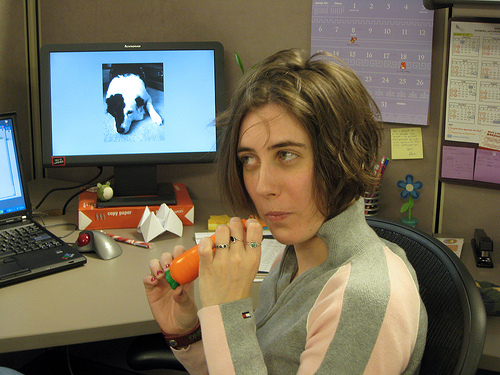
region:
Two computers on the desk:
[0, 30, 240, 283]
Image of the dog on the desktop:
[43, 22, 216, 159]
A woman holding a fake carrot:
[143, 45, 400, 320]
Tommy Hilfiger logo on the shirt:
[237, 303, 259, 321]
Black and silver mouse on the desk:
[70, 219, 133, 266]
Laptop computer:
[0, 115, 87, 275]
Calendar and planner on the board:
[310, 3, 499, 162]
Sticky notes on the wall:
[383, 115, 498, 200]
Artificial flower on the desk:
[395, 165, 421, 225]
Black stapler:
[467, 206, 496, 272]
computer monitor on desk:
[45, 41, 231, 181]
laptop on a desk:
[21, 213, 72, 268]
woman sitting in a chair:
[130, 40, 442, 371]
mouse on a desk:
[82, 223, 119, 259]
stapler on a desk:
[465, 207, 496, 270]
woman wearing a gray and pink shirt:
[130, 35, 431, 370]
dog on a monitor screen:
[103, 52, 171, 133]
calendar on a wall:
[395, 35, 435, 125]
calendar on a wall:
[440, 45, 463, 145]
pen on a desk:
[135, 236, 150, 251]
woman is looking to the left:
[155, 40, 410, 257]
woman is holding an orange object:
[152, 207, 273, 290]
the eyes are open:
[219, 121, 319, 176]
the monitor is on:
[2, 17, 232, 197]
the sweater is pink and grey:
[125, 213, 429, 363]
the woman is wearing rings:
[187, 220, 275, 267]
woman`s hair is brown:
[167, 33, 394, 209]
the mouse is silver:
[71, 213, 124, 275]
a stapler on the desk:
[469, 220, 495, 274]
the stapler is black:
[470, 213, 497, 278]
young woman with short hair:
[140, 46, 430, 373]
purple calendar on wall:
[307, 0, 437, 127]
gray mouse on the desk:
[74, 228, 123, 261]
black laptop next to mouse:
[0, 108, 88, 289]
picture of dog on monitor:
[37, 40, 229, 207]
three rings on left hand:
[197, 214, 266, 306]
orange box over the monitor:
[72, 180, 195, 230]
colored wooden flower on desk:
[395, 173, 424, 233]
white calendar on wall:
[440, 16, 499, 146]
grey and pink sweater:
[166, 195, 430, 373]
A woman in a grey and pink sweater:
[141, 47, 428, 374]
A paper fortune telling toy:
[138, 203, 184, 243]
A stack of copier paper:
[78, 183, 194, 228]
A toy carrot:
[163, 219, 245, 289]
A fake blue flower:
[398, 173, 423, 220]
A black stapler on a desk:
[470, 227, 491, 268]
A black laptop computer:
[0, 111, 88, 289]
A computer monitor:
[40, 42, 221, 207]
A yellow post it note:
[390, 125, 423, 163]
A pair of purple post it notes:
[443, 144, 499, 182]